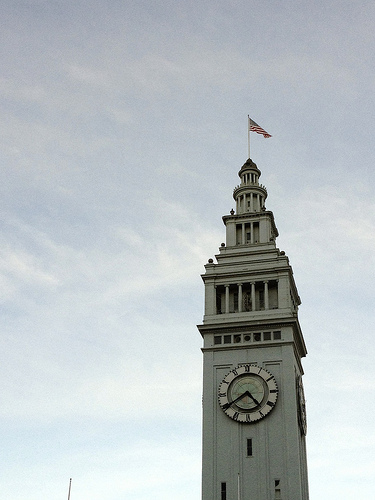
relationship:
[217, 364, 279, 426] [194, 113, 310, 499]
clock on front of tower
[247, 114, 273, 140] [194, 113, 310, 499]
flag on top of tower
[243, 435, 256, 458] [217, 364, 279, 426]
window under clock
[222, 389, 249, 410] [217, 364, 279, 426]
hand on front of clock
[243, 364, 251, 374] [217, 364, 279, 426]
roman numeral on front of clock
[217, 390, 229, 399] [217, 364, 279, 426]
roman numeral on front of clock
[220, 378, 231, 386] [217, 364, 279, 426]
roman numeral on front of clock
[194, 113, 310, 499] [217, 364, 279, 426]
tower has clock